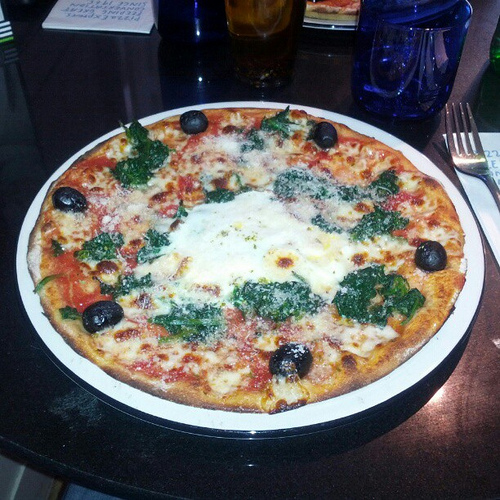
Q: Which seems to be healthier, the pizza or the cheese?
A: The cheese is healthier than the pizza.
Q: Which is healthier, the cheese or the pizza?
A: The cheese is healthier than the pizza.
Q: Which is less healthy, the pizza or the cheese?
A: The pizza is less healthy than the cheese.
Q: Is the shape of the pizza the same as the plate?
A: Yes, both the pizza and the plate are round.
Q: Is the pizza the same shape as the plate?
A: Yes, both the pizza and the plate are round.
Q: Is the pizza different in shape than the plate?
A: No, both the pizza and the plate are round.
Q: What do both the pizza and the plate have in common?
A: The shape, both the pizza and the plate are round.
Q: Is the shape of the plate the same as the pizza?
A: Yes, both the plate and the pizza are round.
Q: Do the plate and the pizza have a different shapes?
A: No, both the plate and the pizza are round.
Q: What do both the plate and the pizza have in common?
A: The shape, both the plate and the pizza are round.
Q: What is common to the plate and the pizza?
A: The shape, both the plate and the pizza are round.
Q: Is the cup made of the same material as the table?
A: No, the cup is made of glass and the table is made of wood.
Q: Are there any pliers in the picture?
A: No, there are no pliers.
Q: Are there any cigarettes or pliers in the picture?
A: No, there are no pliers or cigarettes.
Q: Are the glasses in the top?
A: Yes, the glasses are in the top of the image.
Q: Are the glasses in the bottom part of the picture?
A: No, the glasses are in the top of the image.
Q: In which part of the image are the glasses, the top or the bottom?
A: The glasses are in the top of the image.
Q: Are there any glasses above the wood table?
A: Yes, there are glasses above the table.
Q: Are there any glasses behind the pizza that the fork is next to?
A: Yes, there are glasses behind the pizza.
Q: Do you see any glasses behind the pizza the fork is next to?
A: Yes, there are glasses behind the pizza.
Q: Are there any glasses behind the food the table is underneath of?
A: Yes, there are glasses behind the pizza.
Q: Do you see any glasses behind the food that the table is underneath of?
A: Yes, there are glasses behind the pizza.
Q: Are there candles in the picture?
A: No, there are no candles.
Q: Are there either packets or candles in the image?
A: No, there are no candles or packets.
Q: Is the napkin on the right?
A: Yes, the napkin is on the right of the image.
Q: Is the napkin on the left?
A: No, the napkin is on the right of the image.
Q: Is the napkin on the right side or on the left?
A: The napkin is on the right of the image.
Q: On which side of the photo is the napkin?
A: The napkin is on the right of the image.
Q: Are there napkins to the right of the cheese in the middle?
A: Yes, there is a napkin to the right of the cheese.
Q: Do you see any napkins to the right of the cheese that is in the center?
A: Yes, there is a napkin to the right of the cheese.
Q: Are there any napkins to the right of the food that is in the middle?
A: Yes, there is a napkin to the right of the cheese.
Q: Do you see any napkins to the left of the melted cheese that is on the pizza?
A: No, the napkin is to the right of the cheese.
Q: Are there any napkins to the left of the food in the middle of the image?
A: No, the napkin is to the right of the cheese.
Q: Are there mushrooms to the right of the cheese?
A: No, there is a napkin to the right of the cheese.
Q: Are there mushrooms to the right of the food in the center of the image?
A: No, there is a napkin to the right of the cheese.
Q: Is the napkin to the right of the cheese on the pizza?
A: Yes, the napkin is to the right of the cheese.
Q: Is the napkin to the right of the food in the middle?
A: Yes, the napkin is to the right of the cheese.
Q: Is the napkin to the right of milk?
A: No, the napkin is to the right of the cheese.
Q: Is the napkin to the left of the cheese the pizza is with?
A: No, the napkin is to the right of the cheese.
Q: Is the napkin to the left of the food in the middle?
A: No, the napkin is to the right of the cheese.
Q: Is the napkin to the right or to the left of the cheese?
A: The napkin is to the right of the cheese.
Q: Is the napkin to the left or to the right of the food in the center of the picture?
A: The napkin is to the right of the cheese.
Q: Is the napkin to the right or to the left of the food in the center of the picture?
A: The napkin is to the right of the cheese.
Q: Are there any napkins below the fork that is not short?
A: Yes, there is a napkin below the fork.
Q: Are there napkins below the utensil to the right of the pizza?
A: Yes, there is a napkin below the fork.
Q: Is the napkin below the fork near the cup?
A: Yes, the napkin is below the fork.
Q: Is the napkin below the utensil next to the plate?
A: Yes, the napkin is below the fork.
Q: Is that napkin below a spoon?
A: No, the napkin is below the fork.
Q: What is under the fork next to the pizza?
A: The napkin is under the fork.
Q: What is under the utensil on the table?
A: The napkin is under the fork.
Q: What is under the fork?
A: The napkin is under the fork.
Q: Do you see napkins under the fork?
A: Yes, there is a napkin under the fork.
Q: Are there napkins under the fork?
A: Yes, there is a napkin under the fork.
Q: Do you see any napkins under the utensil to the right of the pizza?
A: Yes, there is a napkin under the fork.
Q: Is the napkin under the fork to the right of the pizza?
A: Yes, the napkin is under the fork.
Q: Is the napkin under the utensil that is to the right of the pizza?
A: Yes, the napkin is under the fork.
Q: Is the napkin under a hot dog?
A: No, the napkin is under the fork.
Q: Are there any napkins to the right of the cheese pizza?
A: Yes, there is a napkin to the right of the pizza.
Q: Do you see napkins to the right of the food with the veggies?
A: Yes, there is a napkin to the right of the pizza.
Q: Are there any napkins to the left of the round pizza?
A: No, the napkin is to the right of the pizza.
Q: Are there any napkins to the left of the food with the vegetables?
A: No, the napkin is to the right of the pizza.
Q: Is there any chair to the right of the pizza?
A: No, there is a napkin to the right of the pizza.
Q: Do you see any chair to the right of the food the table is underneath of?
A: No, there is a napkin to the right of the pizza.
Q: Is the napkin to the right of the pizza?
A: Yes, the napkin is to the right of the pizza.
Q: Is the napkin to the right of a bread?
A: No, the napkin is to the right of the pizza.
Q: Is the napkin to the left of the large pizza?
A: No, the napkin is to the right of the pizza.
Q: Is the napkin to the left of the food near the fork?
A: No, the napkin is to the right of the pizza.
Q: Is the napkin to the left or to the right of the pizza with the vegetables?
A: The napkin is to the right of the pizza.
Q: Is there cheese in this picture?
A: Yes, there is cheese.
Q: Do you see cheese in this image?
A: Yes, there is cheese.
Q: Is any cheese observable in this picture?
A: Yes, there is cheese.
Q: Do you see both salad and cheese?
A: No, there is cheese but no salad.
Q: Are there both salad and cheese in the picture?
A: No, there is cheese but no salad.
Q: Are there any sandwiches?
A: No, there are no sandwiches.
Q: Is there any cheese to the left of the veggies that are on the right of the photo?
A: Yes, there is cheese to the left of the vegetables.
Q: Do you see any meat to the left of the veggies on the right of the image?
A: No, there is cheese to the left of the vegetables.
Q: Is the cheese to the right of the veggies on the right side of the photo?
A: No, the cheese is to the left of the vegetables.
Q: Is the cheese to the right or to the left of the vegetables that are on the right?
A: The cheese is to the left of the vegetables.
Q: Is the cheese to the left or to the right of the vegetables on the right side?
A: The cheese is to the left of the vegetables.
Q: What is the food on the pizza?
A: The food is cheese.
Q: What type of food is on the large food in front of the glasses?
A: The food is cheese.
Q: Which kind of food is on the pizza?
A: The food is cheese.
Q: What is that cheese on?
A: The cheese is on the pizza.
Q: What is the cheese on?
A: The cheese is on the pizza.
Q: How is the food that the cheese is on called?
A: The food is a pizza.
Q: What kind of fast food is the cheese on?
A: The cheese is on the pizza.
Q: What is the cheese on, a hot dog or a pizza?
A: The cheese is on a pizza.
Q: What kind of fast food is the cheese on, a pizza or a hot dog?
A: The cheese is on a pizza.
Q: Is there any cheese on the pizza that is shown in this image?
A: Yes, there is cheese on the pizza.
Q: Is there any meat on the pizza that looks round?
A: No, there is cheese on the pizza.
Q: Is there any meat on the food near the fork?
A: No, there is cheese on the pizza.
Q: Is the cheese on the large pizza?
A: Yes, the cheese is on the pizza.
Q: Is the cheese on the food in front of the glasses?
A: Yes, the cheese is on the pizza.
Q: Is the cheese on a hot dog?
A: No, the cheese is on the pizza.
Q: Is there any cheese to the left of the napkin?
A: Yes, there is cheese to the left of the napkin.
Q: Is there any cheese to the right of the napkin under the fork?
A: No, the cheese is to the left of the napkin.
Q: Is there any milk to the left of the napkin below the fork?
A: No, there is cheese to the left of the napkin.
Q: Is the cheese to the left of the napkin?
A: Yes, the cheese is to the left of the napkin.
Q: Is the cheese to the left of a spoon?
A: No, the cheese is to the left of the napkin.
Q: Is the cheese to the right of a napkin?
A: No, the cheese is to the left of a napkin.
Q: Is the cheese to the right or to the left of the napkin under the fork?
A: The cheese is to the left of the napkin.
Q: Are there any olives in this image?
A: Yes, there are olives.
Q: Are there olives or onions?
A: Yes, there are olives.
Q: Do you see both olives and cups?
A: Yes, there are both olives and a cup.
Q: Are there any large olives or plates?
A: Yes, there are large olives.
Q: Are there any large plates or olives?
A: Yes, there are large olives.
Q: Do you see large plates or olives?
A: Yes, there are large olives.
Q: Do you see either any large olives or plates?
A: Yes, there are large olives.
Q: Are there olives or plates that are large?
A: Yes, the olives are large.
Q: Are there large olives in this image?
A: Yes, there are large olives.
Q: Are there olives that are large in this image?
A: Yes, there are large olives.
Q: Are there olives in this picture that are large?
A: Yes, there are large olives.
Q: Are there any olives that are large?
A: Yes, there are olives that are large.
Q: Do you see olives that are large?
A: Yes, there are olives that are large.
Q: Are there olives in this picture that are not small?
A: Yes, there are large olives.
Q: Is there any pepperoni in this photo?
A: No, there is no pepperoni.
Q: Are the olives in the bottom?
A: Yes, the olives are in the bottom of the image.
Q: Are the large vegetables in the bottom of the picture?
A: Yes, the olives are in the bottom of the image.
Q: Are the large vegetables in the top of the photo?
A: No, the olives are in the bottom of the image.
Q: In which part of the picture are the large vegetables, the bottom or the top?
A: The olives are in the bottom of the image.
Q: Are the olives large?
A: Yes, the olives are large.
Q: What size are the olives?
A: The olives are large.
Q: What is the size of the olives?
A: The olives are large.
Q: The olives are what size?
A: The olives are large.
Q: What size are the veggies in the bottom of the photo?
A: The olives are large.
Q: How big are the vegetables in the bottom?
A: The olives are large.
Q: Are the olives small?
A: No, the olives are large.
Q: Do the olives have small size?
A: No, the olives are large.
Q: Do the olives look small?
A: No, the olives are large.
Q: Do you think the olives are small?
A: No, the olives are large.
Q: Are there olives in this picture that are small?
A: No, there are olives but they are large.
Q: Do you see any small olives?
A: No, there are olives but they are large.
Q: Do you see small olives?
A: No, there are olives but they are large.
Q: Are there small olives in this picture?
A: No, there are olives but they are large.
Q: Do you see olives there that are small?
A: No, there are olives but they are large.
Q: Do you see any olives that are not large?
A: No, there are olives but they are large.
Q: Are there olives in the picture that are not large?
A: No, there are olives but they are large.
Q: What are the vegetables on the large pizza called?
A: The vegetables are olives.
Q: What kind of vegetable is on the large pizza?
A: The vegetables are olives.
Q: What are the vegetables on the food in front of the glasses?
A: The vegetables are olives.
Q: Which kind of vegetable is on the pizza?
A: The vegetables are olives.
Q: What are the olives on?
A: The olives are on the pizza.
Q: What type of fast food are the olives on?
A: The olives are on the pizza.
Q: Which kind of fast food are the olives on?
A: The olives are on the pizza.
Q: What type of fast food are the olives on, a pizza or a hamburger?
A: The olives are on a pizza.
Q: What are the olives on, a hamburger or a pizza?
A: The olives are on a pizza.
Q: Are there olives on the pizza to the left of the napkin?
A: Yes, there are olives on the pizza.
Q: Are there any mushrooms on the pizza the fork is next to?
A: No, there are olives on the pizza.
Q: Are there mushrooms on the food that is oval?
A: No, there are olives on the pizza.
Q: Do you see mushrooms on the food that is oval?
A: No, there are olives on the pizza.